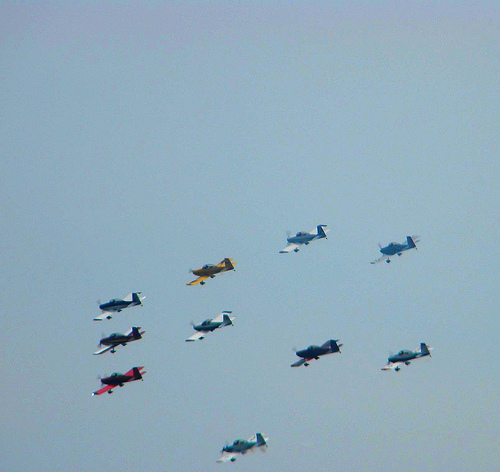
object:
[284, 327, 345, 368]
plane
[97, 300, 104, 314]
propeller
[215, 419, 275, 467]
plane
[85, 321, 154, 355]
plane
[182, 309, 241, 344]
plane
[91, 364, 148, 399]
plane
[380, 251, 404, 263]
wheels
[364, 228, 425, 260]
plane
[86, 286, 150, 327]
plane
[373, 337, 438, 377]
plane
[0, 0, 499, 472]
sky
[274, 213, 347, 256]
plane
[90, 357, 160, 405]
plane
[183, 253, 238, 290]
plane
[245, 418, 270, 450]
tail plane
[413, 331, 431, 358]
tail plane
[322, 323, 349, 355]
tail plane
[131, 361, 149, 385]
tail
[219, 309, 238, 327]
tail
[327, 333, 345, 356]
tail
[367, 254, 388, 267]
wings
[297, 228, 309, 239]
window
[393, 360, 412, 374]
wheels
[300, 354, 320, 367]
wheels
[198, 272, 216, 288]
wheels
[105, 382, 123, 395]
wheels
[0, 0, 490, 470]
air